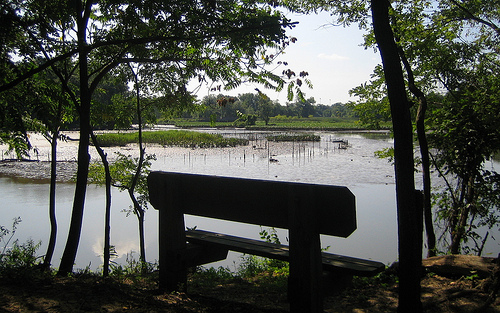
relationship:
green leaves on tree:
[453, 102, 495, 157] [400, 5, 497, 260]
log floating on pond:
[328, 134, 353, 146] [0, 87, 499, 270]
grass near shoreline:
[162, 110, 452, 131] [147, 107, 487, 127]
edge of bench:
[329, 235, 396, 307] [147, 171, 386, 311]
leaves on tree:
[78, 10, 310, 80] [1, 0, 312, 278]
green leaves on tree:
[493, 102, 496, 106] [55, 0, 95, 271]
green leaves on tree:
[493, 102, 496, 106] [428, 0, 499, 256]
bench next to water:
[112, 146, 461, 292] [66, 97, 488, 295]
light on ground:
[420, 249, 489, 311] [5, 256, 496, 308]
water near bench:
[3, 127, 498, 272] [147, 171, 386, 311]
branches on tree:
[58, 136, 146, 268] [1, 0, 312, 278]